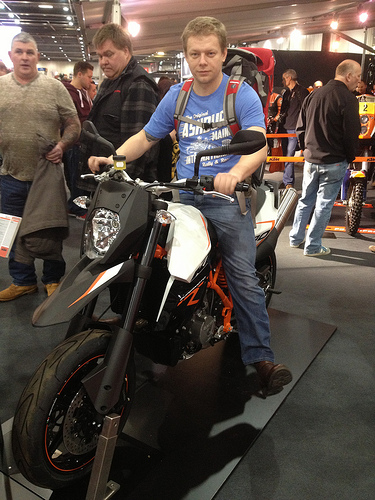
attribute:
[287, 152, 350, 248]
jeans — blue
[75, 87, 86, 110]
string — white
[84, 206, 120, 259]
light — off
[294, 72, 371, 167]
coat — black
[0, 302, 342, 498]
stand — silver, black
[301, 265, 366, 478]
carpet — grey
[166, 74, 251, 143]
bookbag — gray, red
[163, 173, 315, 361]
jeans — blue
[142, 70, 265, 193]
shirt — blue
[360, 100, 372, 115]
2 — black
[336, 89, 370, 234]
bike — dirt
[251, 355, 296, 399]
boot — brown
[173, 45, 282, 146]
backpack — red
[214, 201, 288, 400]
jeans — blue 